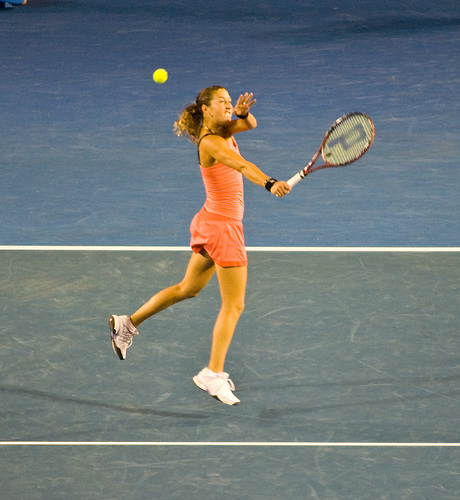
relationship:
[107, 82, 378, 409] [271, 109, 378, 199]
woman has racket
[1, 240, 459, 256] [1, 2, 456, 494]
line on court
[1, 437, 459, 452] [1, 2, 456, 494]
line on court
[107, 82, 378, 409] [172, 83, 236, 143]
woman with hair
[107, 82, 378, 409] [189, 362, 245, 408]
woman has foot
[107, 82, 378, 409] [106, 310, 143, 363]
woman has foot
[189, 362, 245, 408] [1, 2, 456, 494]
foot off ground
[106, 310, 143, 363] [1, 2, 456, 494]
foot off ground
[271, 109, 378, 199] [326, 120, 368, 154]
racket with letter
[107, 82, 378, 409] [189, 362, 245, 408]
woman wearing shoe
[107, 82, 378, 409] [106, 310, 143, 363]
woman wearing shoe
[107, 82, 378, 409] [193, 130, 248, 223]
woman wearing top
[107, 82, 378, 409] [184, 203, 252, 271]
woman wearing shorts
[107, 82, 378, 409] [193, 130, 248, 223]
woman wearing tshirt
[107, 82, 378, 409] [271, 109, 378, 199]
woman wearing racket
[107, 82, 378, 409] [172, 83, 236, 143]
woman has hair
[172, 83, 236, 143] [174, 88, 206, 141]
hair in pony tail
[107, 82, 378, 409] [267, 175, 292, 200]
woman has hand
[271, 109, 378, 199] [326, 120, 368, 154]
racket has letter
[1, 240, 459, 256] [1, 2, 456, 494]
stripe on court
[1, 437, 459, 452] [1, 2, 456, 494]
stripe on court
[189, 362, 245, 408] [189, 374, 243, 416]
shoe with soul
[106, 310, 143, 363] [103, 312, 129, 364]
shoe with soul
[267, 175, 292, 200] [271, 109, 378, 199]
hand holding racket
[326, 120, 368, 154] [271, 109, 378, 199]
p on racket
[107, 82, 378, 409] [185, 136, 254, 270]
girl in outfit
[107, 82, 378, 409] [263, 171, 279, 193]
girl wearing band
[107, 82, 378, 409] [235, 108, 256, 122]
girl wearing band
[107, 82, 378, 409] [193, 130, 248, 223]
girl in top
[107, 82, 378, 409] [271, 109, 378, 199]
girl swings racket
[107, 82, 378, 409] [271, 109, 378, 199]
girl has racket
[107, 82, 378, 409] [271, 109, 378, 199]
girl swinging racket